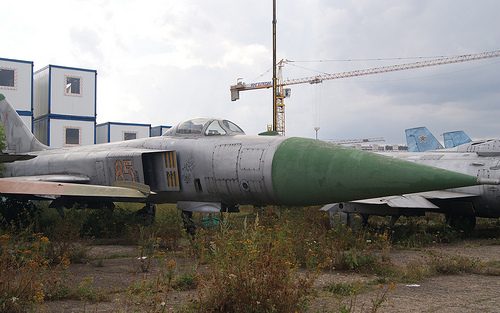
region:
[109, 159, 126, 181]
The number 8 on the side of the plane.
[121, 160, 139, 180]
The number 5 on the side of the plane.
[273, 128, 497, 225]
The green part of the plane.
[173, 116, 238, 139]
The small area of the cockpit where the pilot would sit.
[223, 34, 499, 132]
The crane behind the planes.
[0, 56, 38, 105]
The top left white box.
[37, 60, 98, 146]
The two boxes in behind the plane.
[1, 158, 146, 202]
The side wing of the plane with the green paint.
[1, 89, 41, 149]
The back wing of the plane with the green paint on it.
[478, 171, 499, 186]
The silver tip of the plane with the green paint on it.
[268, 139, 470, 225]
the jet has a green head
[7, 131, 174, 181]
number 85 is written on the side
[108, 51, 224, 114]
the sky is cloudy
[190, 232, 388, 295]
there is vegetation on the ground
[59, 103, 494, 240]
the jets are out of service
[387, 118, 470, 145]
the tail is blue in color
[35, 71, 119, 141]
the containers are white in color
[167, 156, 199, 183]
there is writing on the side of the plane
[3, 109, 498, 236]
there are three planes in the yard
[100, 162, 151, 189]
number 85 is brown in color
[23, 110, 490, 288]
jet with other aircraft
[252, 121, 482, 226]
pointy green nose of jet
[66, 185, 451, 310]
weeds growing under the plane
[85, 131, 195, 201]
boxy opening on side of plane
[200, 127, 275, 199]
riveted panels on plane body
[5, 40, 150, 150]
housing designed in cubes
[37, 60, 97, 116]
square window off center on square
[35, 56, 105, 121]
blue edging on cube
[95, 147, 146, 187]
fading yellow number on plane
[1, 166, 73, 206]
faded red paint on wing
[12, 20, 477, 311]
an old fighter plane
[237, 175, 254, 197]
a hole in the side of the plane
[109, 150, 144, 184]
a number on the side of the plane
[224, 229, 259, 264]
yellow flowers growing in the bushes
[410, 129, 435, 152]
a red star on the tail fin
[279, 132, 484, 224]
a green cone nose of a plane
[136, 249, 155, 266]
white paper on the ground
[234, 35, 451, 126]
a large construction cran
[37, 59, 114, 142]
storage units stacked on top of each other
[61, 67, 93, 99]
a window in the storage container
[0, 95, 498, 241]
jets scrapped and lined up in scrap yard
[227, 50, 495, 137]
large crane for moving heavy objects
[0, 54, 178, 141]
modular building units stacked like blocks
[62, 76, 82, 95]
window in modular unit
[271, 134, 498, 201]
green nose of scrapped jet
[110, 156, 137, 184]
number 85 painted in yellow on side of jet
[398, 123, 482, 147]
blue tails of lined up jets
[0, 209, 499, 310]
hardpan with large weeds growing in it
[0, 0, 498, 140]
overcast sky of almost solid clouds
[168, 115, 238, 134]
airplane cockpit where pilot would sit to fly the jet